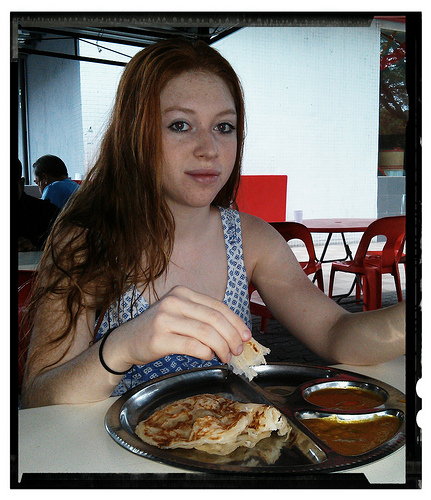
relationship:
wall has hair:
[20, 36, 407, 407] [20, 36, 246, 369]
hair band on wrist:
[98, 328, 132, 377] [86, 320, 140, 388]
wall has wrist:
[20, 36, 407, 407] [86, 320, 140, 388]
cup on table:
[292, 208, 306, 223] [296, 218, 375, 263]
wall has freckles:
[20, 36, 407, 407] [164, 132, 194, 151]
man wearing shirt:
[30, 153, 83, 206] [40, 177, 80, 206]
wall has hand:
[20, 36, 407, 407] [129, 284, 252, 367]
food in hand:
[230, 334, 271, 379] [129, 284, 252, 367]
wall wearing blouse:
[20, 36, 407, 407] [96, 205, 252, 404]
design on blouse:
[231, 298, 238, 307] [96, 205, 252, 404]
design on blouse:
[236, 279, 244, 287] [96, 205, 252, 404]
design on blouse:
[233, 308, 241, 316] [96, 205, 252, 404]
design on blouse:
[122, 311, 131, 321] [96, 205, 252, 404]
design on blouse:
[234, 226, 242, 234] [96, 205, 252, 404]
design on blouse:
[233, 269, 243, 277] [96, 205, 252, 404]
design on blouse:
[218, 206, 226, 214] [96, 205, 252, 404]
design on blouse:
[101, 319, 110, 329] [96, 205, 252, 404]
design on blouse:
[124, 293, 133, 303] [96, 205, 252, 404]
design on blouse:
[220, 213, 225, 221] [96, 205, 252, 404]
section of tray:
[122, 369, 323, 468] [105, 360, 407, 472]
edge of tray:
[105, 388, 141, 461] [105, 360, 407, 472]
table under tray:
[19, 356, 406, 483] [105, 360, 407, 472]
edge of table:
[308, 227, 366, 234] [296, 218, 375, 263]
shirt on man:
[40, 177, 80, 206] [30, 153, 83, 206]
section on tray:
[251, 364, 330, 398] [105, 360, 407, 472]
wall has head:
[20, 36, 407, 407] [114, 38, 241, 209]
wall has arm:
[20, 36, 407, 407] [20, 203, 249, 412]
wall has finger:
[20, 36, 407, 407] [171, 332, 213, 361]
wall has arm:
[20, 36, 407, 407] [253, 214, 407, 367]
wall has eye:
[20, 36, 407, 407] [168, 119, 193, 133]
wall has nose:
[20, 36, 407, 407] [193, 134, 222, 161]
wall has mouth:
[20, 36, 407, 407] [184, 166, 221, 186]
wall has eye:
[20, 36, 407, 407] [211, 122, 234, 134]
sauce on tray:
[303, 418, 400, 454] [105, 360, 407, 472]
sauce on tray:
[307, 387, 386, 407] [105, 360, 407, 472]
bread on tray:
[133, 393, 292, 455] [105, 360, 407, 472]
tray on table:
[105, 360, 407, 472] [19, 356, 406, 483]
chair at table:
[328, 215, 405, 310] [296, 218, 375, 263]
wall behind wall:
[80, 28, 381, 245] [20, 36, 407, 407]